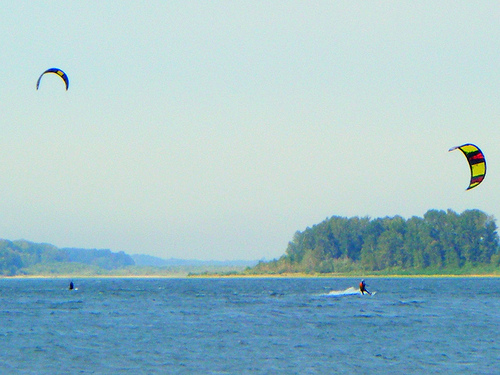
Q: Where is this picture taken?
A: Waterfront.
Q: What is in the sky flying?
A: Kites.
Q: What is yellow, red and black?
A: A kite.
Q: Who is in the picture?
A: Waterboarders.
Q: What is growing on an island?
A: Trees.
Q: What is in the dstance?
A: Hills.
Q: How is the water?
A: Calm.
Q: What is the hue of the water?
A: Aqua.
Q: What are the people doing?
A: Windsurfing.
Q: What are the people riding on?
A: Boards.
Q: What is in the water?
A: A skier.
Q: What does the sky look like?
A: Clear.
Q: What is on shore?
A: A small wooded area.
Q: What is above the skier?
A: A wind sail.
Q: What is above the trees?
A: The sky.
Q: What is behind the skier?
A: A wave of water.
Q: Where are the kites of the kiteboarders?
A: The sky.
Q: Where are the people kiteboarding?
A: The water.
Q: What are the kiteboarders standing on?
A: Kiteboards.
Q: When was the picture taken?
A: Daytime.